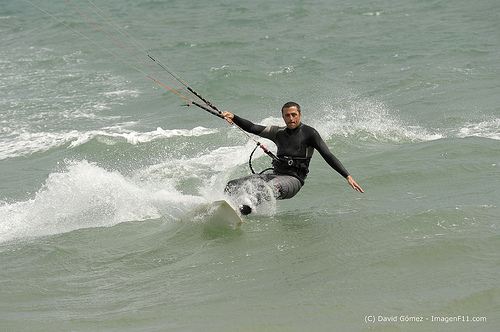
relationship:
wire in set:
[24, 3, 194, 106] [26, 1, 277, 164]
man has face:
[201, 91, 370, 233] [275, 101, 304, 129]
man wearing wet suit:
[201, 91, 370, 233] [232, 94, 350, 204]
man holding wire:
[201, 91, 370, 233] [24, 3, 194, 106]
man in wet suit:
[201, 91, 370, 233] [232, 94, 350, 204]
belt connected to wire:
[266, 155, 311, 178] [26, 1, 277, 164]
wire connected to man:
[24, 3, 194, 106] [201, 91, 370, 233]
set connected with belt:
[26, 1, 277, 164] [266, 155, 311, 178]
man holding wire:
[201, 91, 370, 233] [191, 102, 271, 152]